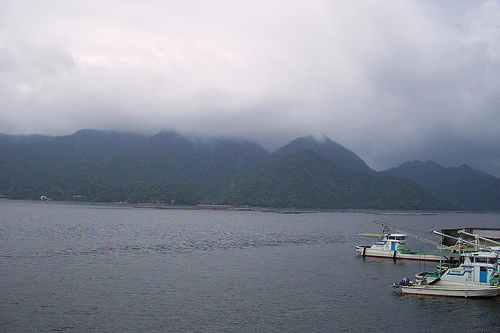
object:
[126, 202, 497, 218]
landings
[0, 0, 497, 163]
fog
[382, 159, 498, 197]
hill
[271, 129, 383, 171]
mountain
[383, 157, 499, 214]
hills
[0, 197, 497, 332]
water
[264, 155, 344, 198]
tree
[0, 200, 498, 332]
sea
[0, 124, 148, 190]
mountain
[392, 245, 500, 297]
boat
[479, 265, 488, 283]
door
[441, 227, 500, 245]
structure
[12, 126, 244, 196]
hill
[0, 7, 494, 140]
foggysky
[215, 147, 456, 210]
hill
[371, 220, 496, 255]
crane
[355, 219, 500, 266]
boat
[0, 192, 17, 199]
homes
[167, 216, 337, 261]
ripples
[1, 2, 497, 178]
sky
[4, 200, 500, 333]
surface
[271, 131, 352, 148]
hilltops